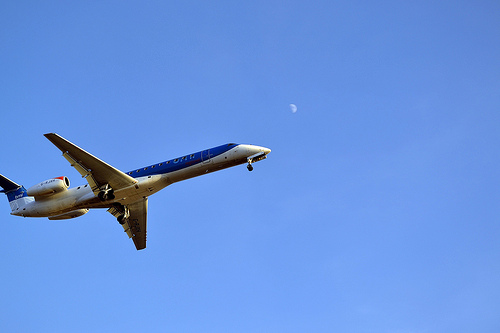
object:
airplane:
[0, 132, 272, 251]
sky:
[0, 1, 499, 333]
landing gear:
[115, 207, 131, 226]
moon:
[289, 102, 299, 116]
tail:
[0, 169, 33, 221]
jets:
[25, 175, 70, 199]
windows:
[190, 154, 194, 159]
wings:
[28, 127, 136, 194]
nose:
[265, 147, 272, 154]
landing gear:
[244, 158, 254, 172]